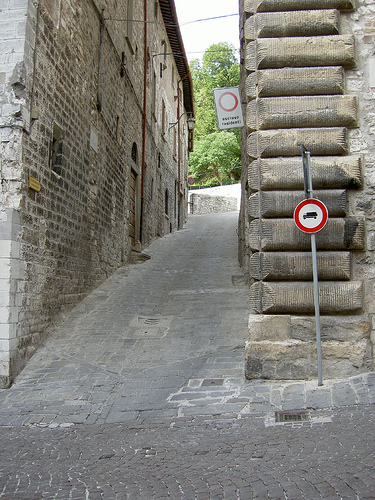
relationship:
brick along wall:
[242, 96, 354, 132] [243, 1, 374, 385]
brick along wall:
[249, 156, 366, 192] [243, 1, 374, 385]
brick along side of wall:
[242, 96, 354, 132] [243, 1, 374, 385]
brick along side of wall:
[249, 156, 366, 192] [243, 1, 374, 385]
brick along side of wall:
[241, 7, 342, 31] [243, 1, 374, 385]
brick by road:
[249, 156, 366, 192] [4, 212, 374, 498]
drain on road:
[266, 404, 313, 424] [4, 212, 374, 498]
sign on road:
[293, 199, 329, 235] [4, 212, 374, 498]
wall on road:
[13, 5, 194, 400] [4, 212, 374, 498]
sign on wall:
[213, 86, 250, 128] [243, 1, 374, 385]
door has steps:
[124, 170, 142, 255] [124, 243, 155, 266]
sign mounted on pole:
[293, 199, 329, 235] [298, 148, 326, 388]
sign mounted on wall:
[213, 86, 250, 128] [243, 1, 374, 385]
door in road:
[124, 170, 142, 255] [4, 212, 374, 498]